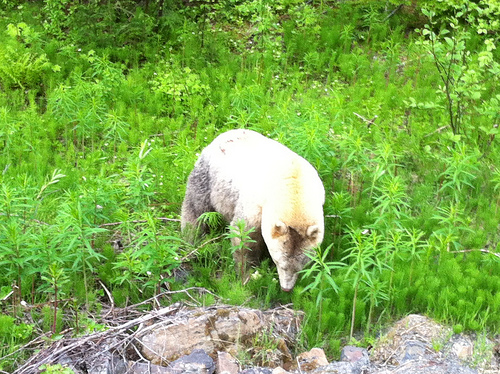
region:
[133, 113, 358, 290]
White bear in the grass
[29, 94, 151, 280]
Green vegetation in the field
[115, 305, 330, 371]
Pile of rocks in front of bear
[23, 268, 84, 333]
Twigs in the form of a cross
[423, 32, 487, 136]
Small tree behind bear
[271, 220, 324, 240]
Two ears of bear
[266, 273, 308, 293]
white nose of bear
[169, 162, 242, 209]
Grey hind part of bear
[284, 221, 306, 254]
Brown fur on bear's head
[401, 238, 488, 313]
Thick green weeds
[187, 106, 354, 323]
bear in the grass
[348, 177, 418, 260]
grass next to the bear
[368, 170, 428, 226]
tall grass next to bear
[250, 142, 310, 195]
fur on the bear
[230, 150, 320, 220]
light fur on the bear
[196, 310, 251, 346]
rocks next to the bear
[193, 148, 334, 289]
bear wandering around grass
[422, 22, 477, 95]
leaves on the branch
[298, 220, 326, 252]
ear of the bear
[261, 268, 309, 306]
nose of the bear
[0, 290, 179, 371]
a pile of sticks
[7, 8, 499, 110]
overgrown plants in a forest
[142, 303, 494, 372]
a pile of rocks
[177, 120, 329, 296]
a lightly colored bear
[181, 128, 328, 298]
an albino bear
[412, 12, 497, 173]
a young tree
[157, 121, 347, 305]
a bear looking for food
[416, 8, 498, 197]
a tree sprout in a forest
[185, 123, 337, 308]
a bear foraging for food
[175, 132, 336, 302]
a bear with a red stripe down its back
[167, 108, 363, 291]
a bear between plants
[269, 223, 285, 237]
right ear of bear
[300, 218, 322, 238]
left ear of bear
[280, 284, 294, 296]
nose of the bear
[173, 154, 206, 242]
back right leg of bear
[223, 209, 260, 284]
front right leg of bear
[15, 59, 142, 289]
a field of various plants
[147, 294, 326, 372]
rocks and stones in front of bear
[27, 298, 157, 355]
group of tree branches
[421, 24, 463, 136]
the branch of a plant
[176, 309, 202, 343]
part of a stone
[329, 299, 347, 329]
part of a plant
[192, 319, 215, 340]
part of a stone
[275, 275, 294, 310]
part of a nose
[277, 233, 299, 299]
part of a head